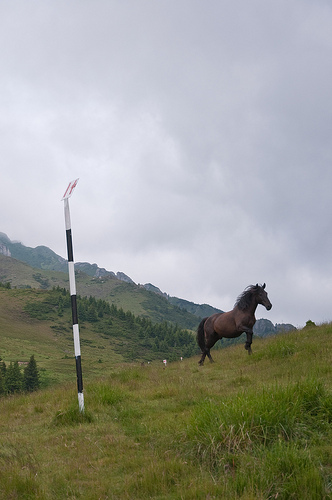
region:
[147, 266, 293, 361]
this is a horse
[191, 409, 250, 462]
a patch of grass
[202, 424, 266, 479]
a patch of grass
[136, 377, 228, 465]
a patch of grass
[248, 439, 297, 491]
a patch of grass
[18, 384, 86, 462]
a patch of grass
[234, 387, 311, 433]
a patch of grass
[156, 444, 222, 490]
a patch of grass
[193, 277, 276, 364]
The horse is walking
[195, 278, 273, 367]
The horse is black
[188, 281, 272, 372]
The horse is on a grassy hill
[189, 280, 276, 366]
The horse is going up the hill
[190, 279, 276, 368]
The horse is on top of grass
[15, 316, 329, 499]
The hill is grassy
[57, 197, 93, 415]
The pole is black and white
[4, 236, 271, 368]
Mountains with trees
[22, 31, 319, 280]
The sky is cloudy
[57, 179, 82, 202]
Red writing on top of pole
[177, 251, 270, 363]
Dark brown horse in a field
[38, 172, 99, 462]
White and black post in the ground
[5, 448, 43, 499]
Tall green grass in field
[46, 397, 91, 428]
Tall green grass in field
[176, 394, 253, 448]
Tall green grass in field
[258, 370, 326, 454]
Tall green grass in field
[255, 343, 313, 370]
Tall green grass in field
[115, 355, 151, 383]
Tall green grass in field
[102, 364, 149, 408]
Tall green grass in field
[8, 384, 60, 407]
Tall green grass in field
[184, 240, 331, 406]
Horse in the field.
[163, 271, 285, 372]
Brown horse in the field.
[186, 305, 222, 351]
Tail on the horse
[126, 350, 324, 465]
Long grass in the field.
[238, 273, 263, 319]
Mane on the horse.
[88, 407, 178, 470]
Short grass in the field.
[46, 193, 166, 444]
Black and white pole.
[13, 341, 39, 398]
Green pine tree.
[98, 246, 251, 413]
Mountains in the background.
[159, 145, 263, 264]
White clouds in the blue sky.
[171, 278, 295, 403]
a brown horse on a green hillside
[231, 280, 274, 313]
dark mane on a brown horse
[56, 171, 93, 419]
black and white striped post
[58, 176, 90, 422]
marker number on top of a pole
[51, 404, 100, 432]
tufts of long grass around the base of a post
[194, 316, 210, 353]
long bushy horse tail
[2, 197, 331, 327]
dark overcast sky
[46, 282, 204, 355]
trees growing on a hillside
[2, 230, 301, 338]
mountains in the background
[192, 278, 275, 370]
a brown horse is climbing a hill